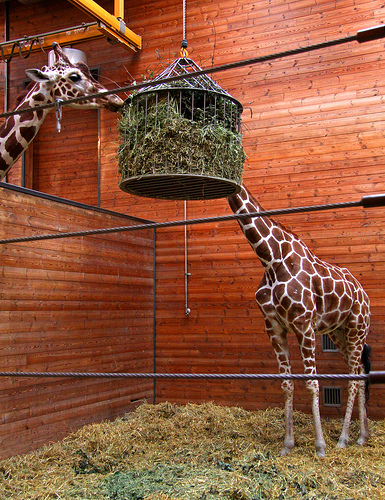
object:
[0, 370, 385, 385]
let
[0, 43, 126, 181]
giraffe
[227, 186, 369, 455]
body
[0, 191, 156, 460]
wall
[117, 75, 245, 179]
food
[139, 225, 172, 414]
corner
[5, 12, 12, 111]
pipe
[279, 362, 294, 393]
knee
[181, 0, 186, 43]
rope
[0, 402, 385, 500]
ground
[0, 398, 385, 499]
hay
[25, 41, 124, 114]
head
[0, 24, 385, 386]
pen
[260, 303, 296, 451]
leg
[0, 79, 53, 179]
neck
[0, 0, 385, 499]
background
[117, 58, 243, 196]
basket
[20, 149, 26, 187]
vents